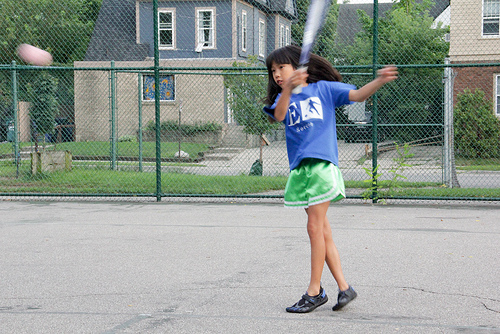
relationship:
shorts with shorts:
[280, 159, 342, 210] [283, 159, 346, 210]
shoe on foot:
[286, 286, 329, 313] [289, 286, 327, 316]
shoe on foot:
[286, 286, 329, 313] [333, 280, 356, 308]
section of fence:
[375, 61, 459, 193] [405, 72, 497, 192]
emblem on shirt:
[264, 101, 334, 128] [259, 68, 364, 168]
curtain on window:
[195, 9, 212, 53] [196, 5, 223, 52]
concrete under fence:
[1, 197, 498, 330] [10, 67, 263, 196]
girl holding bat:
[257, 45, 399, 314] [290, 0, 332, 95]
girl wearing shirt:
[262, 44, 365, 318] [255, 73, 363, 163]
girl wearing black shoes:
[257, 45, 399, 314] [284, 284, 357, 314]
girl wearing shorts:
[257, 45, 399, 314] [280, 158, 347, 209]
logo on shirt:
[285, 97, 323, 132] [262, 80, 357, 166]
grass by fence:
[97, 167, 136, 184] [2, 8, 497, 191]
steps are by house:
[185, 134, 248, 166] [71, 5, 267, 172]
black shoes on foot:
[331, 284, 358, 310] [332, 283, 358, 312]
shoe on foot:
[285, 283, 329, 312] [285, 288, 330, 316]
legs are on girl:
[299, 193, 351, 293] [257, 45, 399, 314]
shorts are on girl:
[283, 159, 346, 210] [257, 45, 399, 314]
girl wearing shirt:
[262, 44, 365, 318] [279, 86, 351, 161]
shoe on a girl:
[286, 286, 329, 313] [262, 40, 357, 311]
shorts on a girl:
[283, 159, 346, 210] [257, 45, 399, 314]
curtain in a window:
[143, 75, 172, 98] [138, 72, 174, 103]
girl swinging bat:
[257, 45, 399, 314] [288, 3, 346, 78]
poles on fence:
[128, 70, 208, 181] [57, 60, 304, 187]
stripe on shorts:
[326, 165, 346, 197] [274, 152, 349, 214]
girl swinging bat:
[257, 45, 399, 314] [288, 0, 328, 94]